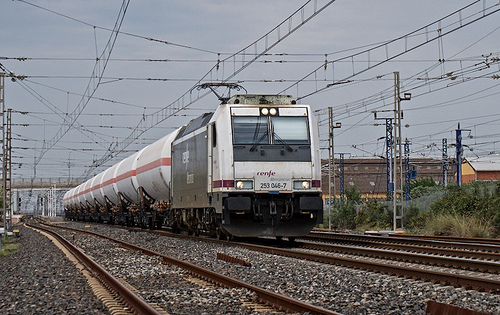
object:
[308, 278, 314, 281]
stone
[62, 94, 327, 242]
train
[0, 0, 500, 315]
scene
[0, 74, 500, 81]
power lines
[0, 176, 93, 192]
bridge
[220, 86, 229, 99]
wires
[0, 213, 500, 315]
trainyard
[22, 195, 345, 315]
set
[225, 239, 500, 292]
set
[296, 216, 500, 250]
set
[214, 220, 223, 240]
wheels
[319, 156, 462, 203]
building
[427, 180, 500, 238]
bushes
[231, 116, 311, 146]
window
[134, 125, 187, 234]
car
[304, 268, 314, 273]
rocks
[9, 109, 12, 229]
poles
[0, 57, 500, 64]
cables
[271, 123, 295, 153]
wipers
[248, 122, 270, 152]
wipers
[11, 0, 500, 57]
wires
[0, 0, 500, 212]
sky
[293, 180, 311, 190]
headlight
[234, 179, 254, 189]
headlight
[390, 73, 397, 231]
pole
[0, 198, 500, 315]
ground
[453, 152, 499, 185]
building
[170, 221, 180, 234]
wheels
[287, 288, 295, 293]
stones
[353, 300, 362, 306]
stones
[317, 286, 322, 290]
stones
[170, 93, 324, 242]
train car